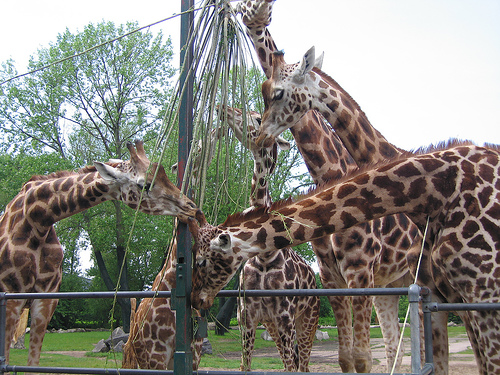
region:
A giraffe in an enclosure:
[1, 135, 198, 374]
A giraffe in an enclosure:
[121, 122, 221, 369]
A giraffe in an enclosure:
[210, 97, 318, 372]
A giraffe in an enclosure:
[228, 0, 420, 374]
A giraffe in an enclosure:
[183, 131, 498, 373]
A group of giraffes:
[0, 0, 499, 372]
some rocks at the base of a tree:
[91, 324, 130, 354]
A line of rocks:
[25, 326, 110, 335]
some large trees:
[1, 20, 322, 352]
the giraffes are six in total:
[8, 69, 495, 364]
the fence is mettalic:
[308, 284, 413, 296]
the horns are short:
[124, 127, 149, 188]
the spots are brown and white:
[349, 189, 396, 216]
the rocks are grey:
[95, 325, 125, 360]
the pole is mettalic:
[178, 180, 193, 308]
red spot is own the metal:
[175, 159, 192, 184]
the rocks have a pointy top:
[98, 321, 128, 358]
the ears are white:
[298, 42, 326, 89]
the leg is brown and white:
[379, 303, 412, 356]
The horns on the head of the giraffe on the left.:
[125, 132, 145, 157]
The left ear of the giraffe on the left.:
[96, 159, 126, 187]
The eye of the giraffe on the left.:
[137, 181, 147, 188]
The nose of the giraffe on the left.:
[183, 200, 195, 208]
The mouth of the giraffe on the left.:
[181, 213, 197, 220]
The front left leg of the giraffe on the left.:
[3, 289, 22, 371]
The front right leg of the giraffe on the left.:
[32, 299, 49, 366]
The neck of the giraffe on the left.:
[40, 170, 110, 214]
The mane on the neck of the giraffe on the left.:
[36, 162, 118, 177]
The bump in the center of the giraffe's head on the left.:
[150, 162, 163, 178]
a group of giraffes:
[0, 3, 499, 369]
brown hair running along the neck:
[315, 66, 406, 136]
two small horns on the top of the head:
[125, 135, 152, 160]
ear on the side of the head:
[87, 156, 122, 182]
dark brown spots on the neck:
[226, 148, 457, 258]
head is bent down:
[172, 143, 445, 327]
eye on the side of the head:
[269, 87, 285, 104]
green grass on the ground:
[8, 321, 338, 373]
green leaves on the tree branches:
[0, 23, 177, 155]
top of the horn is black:
[269, 46, 285, 60]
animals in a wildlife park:
[18, 6, 488, 361]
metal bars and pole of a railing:
[0, 281, 190, 371]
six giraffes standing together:
[35, 4, 447, 363]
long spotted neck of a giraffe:
[240, 176, 465, 216]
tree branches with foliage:
[185, 0, 245, 125]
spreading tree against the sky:
[20, 15, 175, 150]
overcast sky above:
[360, 10, 496, 105]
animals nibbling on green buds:
[111, 130, 237, 320]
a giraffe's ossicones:
[120, 135, 145, 156]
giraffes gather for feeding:
[63, 5, 436, 365]